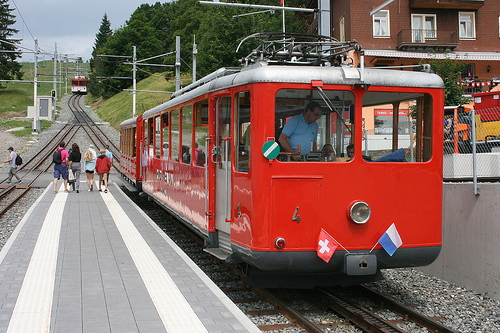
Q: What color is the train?
A: Red.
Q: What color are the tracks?
A: Brown.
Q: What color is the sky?
A: Blue.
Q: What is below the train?
A: Rail tracks.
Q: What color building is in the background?
A: Brown.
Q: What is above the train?
A: Powerlines.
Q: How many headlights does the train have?
A: 1.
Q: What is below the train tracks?
A: Gravel.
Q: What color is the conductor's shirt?
A: Blue.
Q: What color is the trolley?
A: Red.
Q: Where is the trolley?
A: On the track.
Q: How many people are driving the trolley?
A: One.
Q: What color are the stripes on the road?
A: White.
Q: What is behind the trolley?
A: Trees.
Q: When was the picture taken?
A: Daytime.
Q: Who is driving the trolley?
A: A man.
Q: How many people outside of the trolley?
A: 6.